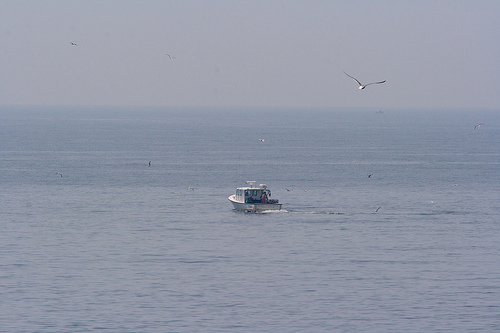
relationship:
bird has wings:
[339, 71, 386, 92] [342, 69, 386, 86]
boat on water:
[226, 179, 282, 215] [1, 105, 500, 332]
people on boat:
[260, 192, 268, 203] [226, 179, 282, 215]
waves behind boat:
[259, 208, 343, 218] [226, 179, 282, 215]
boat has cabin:
[226, 179, 282, 215] [235, 185, 267, 201]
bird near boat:
[339, 71, 386, 92] [226, 179, 282, 215]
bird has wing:
[339, 71, 386, 92] [365, 79, 385, 90]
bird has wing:
[339, 71, 386, 92] [341, 70, 361, 85]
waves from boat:
[259, 208, 343, 218] [226, 179, 282, 215]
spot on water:
[366, 174, 371, 179] [1, 105, 500, 332]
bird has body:
[339, 71, 386, 92] [357, 84, 366, 92]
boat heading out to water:
[226, 179, 282, 215] [1, 105, 500, 332]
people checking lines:
[260, 192, 268, 203] [267, 188, 273, 199]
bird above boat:
[339, 71, 386, 92] [226, 179, 282, 215]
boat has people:
[226, 179, 282, 215] [260, 192, 268, 203]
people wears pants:
[259, 183, 272, 203] [261, 196, 266, 204]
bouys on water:
[148, 160, 153, 168] [1, 105, 500, 332]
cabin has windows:
[235, 185, 267, 201] [235, 188, 243, 197]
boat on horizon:
[226, 179, 282, 215] [2, 80, 498, 122]